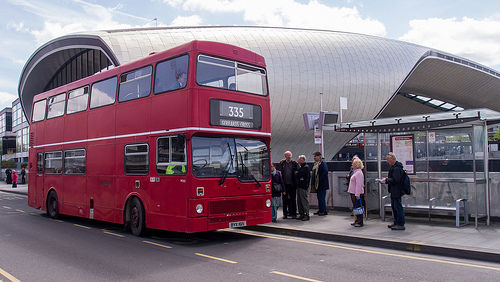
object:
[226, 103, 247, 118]
number 335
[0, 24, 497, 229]
building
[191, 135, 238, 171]
window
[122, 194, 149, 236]
tire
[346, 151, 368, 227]
person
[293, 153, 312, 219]
person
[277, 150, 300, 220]
person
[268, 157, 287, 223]
person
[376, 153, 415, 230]
man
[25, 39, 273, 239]
bus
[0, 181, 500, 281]
road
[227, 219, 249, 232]
license plate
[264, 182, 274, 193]
headlight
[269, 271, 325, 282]
painted lines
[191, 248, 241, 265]
painted lines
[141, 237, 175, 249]
painted lines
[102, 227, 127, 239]
painted lines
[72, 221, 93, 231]
painted lines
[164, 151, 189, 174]
bus driver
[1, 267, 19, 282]
line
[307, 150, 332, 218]
people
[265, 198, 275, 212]
light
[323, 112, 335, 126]
camera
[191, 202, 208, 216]
bus headlight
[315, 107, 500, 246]
stop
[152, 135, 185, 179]
windows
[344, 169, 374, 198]
jacket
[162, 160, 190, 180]
jacket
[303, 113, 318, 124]
camera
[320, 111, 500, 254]
bus station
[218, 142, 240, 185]
wipers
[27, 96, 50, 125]
windows